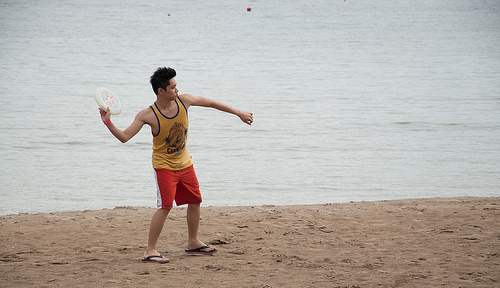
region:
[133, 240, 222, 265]
Man wearing flip flops.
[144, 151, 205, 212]
Man wearing red shorts.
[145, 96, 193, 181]
Man wearing yellow tank top.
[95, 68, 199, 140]
Man holding a frisbee.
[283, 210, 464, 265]
Tan sand on the beach.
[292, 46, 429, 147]
Calm water in the background.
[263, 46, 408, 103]
Blue green ocean water.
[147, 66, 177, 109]
Man has black hair.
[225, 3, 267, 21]
Little red ball in the ocean.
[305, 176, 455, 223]
Where the sand and water meet.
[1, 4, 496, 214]
A peaceful water field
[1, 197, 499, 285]
Dirt ground by the water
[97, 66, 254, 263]
Man playing Frisbee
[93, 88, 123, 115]
Frisbee in the man's hand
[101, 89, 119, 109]
Picture on the Frisbee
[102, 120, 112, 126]
Red band on the man's wrist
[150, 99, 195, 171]
Yellow shirt on the man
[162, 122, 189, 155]
Picture on the man's shirt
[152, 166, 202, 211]
Red shorts on the man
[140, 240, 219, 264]
Flip flops on the man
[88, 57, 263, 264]
man throwing a frisbee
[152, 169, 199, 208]
red and white shorts of man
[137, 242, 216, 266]
flip flops of man throwing frisbee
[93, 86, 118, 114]
white frisbee man is throwing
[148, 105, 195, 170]
yellow tank top with black trim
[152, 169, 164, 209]
white stripe on red shorts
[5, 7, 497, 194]
calm waters behind man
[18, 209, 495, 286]
sand man is standing on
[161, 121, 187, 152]
black outline design on man's shirt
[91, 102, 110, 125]
hand holding white frisbee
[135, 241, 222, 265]
Man is wearing shoes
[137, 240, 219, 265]
Man is wearing sandals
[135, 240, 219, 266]
Man is wearing flip flops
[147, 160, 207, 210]
Man is wearing shorts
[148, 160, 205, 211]
Man is wearing red and white shorts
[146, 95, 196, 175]
Man is wearing a shirt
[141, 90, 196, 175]
Man is wearing a yellow shirt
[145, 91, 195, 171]
Man is wearing a yellow tank top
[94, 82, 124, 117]
Man is holding a frisbee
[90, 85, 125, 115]
Man is holding a white frisbee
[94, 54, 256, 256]
Man is on the beach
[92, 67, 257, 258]
Man is playing frisbee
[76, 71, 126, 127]
Frisbee in the man's right hand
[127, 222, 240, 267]
Man is wearing flip flops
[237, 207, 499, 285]
The shore is covered in sand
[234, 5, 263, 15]
Red buoy in the water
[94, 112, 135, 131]
Orange bracelet on the man's wrist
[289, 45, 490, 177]
The water is calm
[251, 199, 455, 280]
Footprints all over the sand